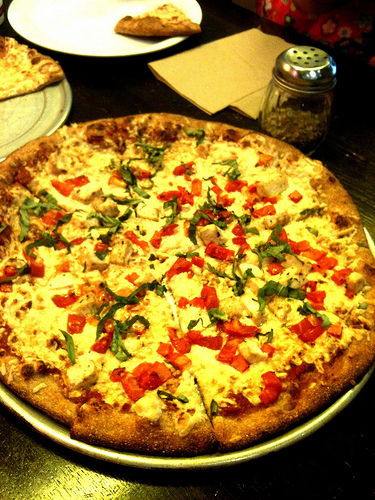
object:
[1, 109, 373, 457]
pizza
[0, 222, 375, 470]
tray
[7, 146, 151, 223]
toppings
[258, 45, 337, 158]
shaker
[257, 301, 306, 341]
oregano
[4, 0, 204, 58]
plate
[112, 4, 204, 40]
slice of pizza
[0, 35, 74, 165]
pan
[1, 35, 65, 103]
slice of pizza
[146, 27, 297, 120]
napkin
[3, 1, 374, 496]
table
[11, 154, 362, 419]
chicken topping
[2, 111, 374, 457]
crust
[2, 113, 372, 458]
slices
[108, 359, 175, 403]
tomatoes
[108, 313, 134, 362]
green toppings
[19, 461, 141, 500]
light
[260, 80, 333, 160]
glass